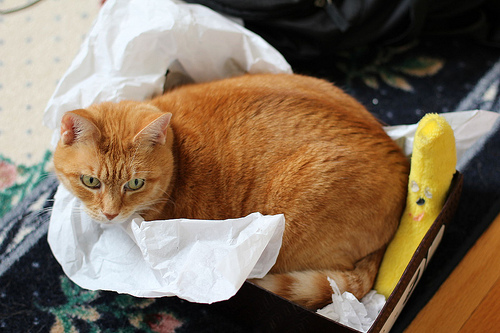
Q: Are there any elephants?
A: No, there are no elephants.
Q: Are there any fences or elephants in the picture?
A: No, there are no elephants or fences.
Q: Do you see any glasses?
A: No, there are no glasses.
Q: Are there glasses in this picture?
A: No, there are no glasses.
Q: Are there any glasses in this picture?
A: No, there are no glasses.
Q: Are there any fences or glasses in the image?
A: No, there are no glasses or fences.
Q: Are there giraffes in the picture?
A: No, there are no giraffes.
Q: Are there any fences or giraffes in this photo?
A: No, there are no giraffes or fences.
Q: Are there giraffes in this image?
A: No, there are no giraffes.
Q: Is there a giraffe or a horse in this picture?
A: No, there are no giraffes or horses.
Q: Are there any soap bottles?
A: No, there are no soap bottles.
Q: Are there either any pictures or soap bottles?
A: No, there are no soap bottles or pictures.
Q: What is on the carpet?
A: The box is on the carpet.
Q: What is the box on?
A: The box is on the carpet.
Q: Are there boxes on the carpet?
A: Yes, there is a box on the carpet.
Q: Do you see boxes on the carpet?
A: Yes, there is a box on the carpet.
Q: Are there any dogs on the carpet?
A: No, there is a box on the carpet.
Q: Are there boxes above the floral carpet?
A: Yes, there is a box above the carpet.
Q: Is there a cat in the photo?
A: Yes, there is a cat.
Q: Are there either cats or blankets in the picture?
A: Yes, there is a cat.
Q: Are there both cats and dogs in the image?
A: No, there is a cat but no dogs.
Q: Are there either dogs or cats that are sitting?
A: Yes, the cat is sitting.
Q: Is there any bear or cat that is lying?
A: Yes, the cat is lying.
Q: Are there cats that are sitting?
A: Yes, there is a cat that is sitting.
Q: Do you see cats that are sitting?
A: Yes, there is a cat that is sitting.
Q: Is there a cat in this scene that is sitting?
A: Yes, there is a cat that is sitting.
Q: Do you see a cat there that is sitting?
A: Yes, there is a cat that is sitting.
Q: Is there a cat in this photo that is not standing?
A: Yes, there is a cat that is sitting.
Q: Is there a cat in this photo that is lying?
A: Yes, there is a cat that is lying.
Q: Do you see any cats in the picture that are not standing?
A: Yes, there is a cat that is lying .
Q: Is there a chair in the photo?
A: No, there are no chairs.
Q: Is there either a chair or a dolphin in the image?
A: No, there are no chairs or dolphins.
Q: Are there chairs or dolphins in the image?
A: No, there are no chairs or dolphins.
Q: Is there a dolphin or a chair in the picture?
A: No, there are no chairs or dolphins.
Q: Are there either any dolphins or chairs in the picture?
A: No, there are no chairs or dolphins.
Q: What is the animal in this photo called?
A: The animal is a cat.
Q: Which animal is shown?
A: The animal is a cat.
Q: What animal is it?
A: The animal is a cat.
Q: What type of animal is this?
A: This is a cat.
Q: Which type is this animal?
A: This is a cat.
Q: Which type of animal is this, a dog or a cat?
A: This is a cat.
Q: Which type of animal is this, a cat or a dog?
A: This is a cat.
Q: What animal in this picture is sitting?
A: The animal is a cat.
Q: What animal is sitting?
A: The animal is a cat.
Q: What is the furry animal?
A: The animal is a cat.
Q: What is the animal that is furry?
A: The animal is a cat.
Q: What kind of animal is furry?
A: The animal is a cat.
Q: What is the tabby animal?
A: The animal is a cat.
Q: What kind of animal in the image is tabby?
A: The animal is a cat.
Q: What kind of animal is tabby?
A: The animal is a cat.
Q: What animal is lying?
A: The animal is a cat.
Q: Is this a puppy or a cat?
A: This is a cat.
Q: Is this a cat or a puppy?
A: This is a cat.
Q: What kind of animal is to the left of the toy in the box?
A: The animal is a cat.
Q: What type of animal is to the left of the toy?
A: The animal is a cat.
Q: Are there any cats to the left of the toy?
A: Yes, there is a cat to the left of the toy.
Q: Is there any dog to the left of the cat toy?
A: No, there is a cat to the left of the toy.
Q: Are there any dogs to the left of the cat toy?
A: No, there is a cat to the left of the toy.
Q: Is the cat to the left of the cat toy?
A: Yes, the cat is to the left of the toy.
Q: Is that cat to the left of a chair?
A: No, the cat is to the left of the toy.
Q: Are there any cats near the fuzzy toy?
A: Yes, there is a cat near the toy.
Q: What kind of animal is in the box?
A: The animal is a cat.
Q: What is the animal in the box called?
A: The animal is a cat.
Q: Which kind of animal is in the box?
A: The animal is a cat.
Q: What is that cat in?
A: The cat is in the box.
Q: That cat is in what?
A: The cat is in the box.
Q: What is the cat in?
A: The cat is in the box.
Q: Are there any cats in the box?
A: Yes, there is a cat in the box.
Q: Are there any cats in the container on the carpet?
A: Yes, there is a cat in the box.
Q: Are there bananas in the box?
A: No, there is a cat in the box.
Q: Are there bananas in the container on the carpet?
A: No, there is a cat in the box.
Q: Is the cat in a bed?
A: No, the cat is in the box.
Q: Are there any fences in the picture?
A: No, there are no fences.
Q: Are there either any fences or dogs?
A: No, there are no fences or dogs.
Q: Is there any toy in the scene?
A: Yes, there is a toy.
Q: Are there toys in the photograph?
A: Yes, there is a toy.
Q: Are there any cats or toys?
A: Yes, there is a toy.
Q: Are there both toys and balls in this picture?
A: No, there is a toy but no balls.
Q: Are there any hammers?
A: No, there are no hammers.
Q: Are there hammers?
A: No, there are no hammers.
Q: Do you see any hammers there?
A: No, there are no hammers.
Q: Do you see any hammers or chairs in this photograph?
A: No, there are no hammers or chairs.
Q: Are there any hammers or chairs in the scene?
A: No, there are no hammers or chairs.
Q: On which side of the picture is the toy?
A: The toy is on the right of the image.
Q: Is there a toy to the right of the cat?
A: Yes, there is a toy to the right of the cat.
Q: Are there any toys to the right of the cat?
A: Yes, there is a toy to the right of the cat.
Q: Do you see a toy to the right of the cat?
A: Yes, there is a toy to the right of the cat.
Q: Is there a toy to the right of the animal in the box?
A: Yes, there is a toy to the right of the cat.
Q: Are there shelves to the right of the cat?
A: No, there is a toy to the right of the cat.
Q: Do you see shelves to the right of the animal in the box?
A: No, there is a toy to the right of the cat.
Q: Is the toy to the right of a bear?
A: No, the toy is to the right of the cat.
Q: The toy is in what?
A: The toy is in the box.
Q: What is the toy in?
A: The toy is in the box.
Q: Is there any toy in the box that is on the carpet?
A: Yes, there is a toy in the box.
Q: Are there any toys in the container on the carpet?
A: Yes, there is a toy in the box.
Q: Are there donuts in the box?
A: No, there is a toy in the box.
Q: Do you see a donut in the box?
A: No, there is a toy in the box.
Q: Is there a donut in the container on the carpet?
A: No, there is a toy in the box.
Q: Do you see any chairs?
A: No, there are no chairs.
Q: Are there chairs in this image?
A: No, there are no chairs.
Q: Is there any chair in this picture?
A: No, there are no chairs.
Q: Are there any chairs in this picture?
A: No, there are no chairs.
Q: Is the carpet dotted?
A: Yes, the carpet is dotted.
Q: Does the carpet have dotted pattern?
A: Yes, the carpet is dotted.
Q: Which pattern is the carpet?
A: The carpet is dotted.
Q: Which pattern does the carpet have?
A: The carpet has dotted pattern.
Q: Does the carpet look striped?
A: No, the carpet is dotted.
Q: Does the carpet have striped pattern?
A: No, the carpet is dotted.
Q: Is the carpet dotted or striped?
A: The carpet is dotted.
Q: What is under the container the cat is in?
A: The carpet is under the box.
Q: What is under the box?
A: The carpet is under the box.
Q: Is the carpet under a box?
A: Yes, the carpet is under a box.